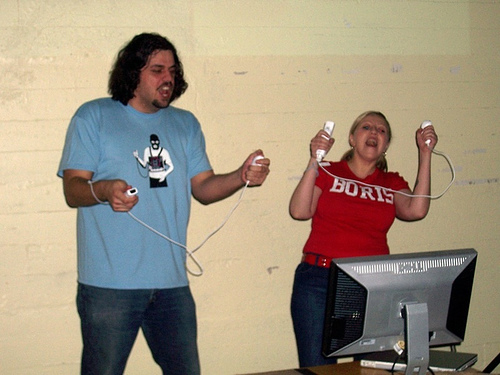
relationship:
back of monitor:
[369, 272, 454, 302] [322, 248, 480, 359]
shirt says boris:
[302, 160, 410, 261] [328, 174, 395, 207]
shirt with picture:
[57, 98, 215, 290] [132, 132, 177, 188]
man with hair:
[58, 34, 271, 375] [108, 32, 188, 108]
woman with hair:
[287, 110, 439, 370] [342, 110, 391, 174]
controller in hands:
[125, 186, 140, 197] [100, 150, 272, 214]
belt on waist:
[300, 251, 332, 270] [302, 241, 393, 275]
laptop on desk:
[360, 352, 479, 372] [234, 362, 489, 374]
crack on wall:
[453, 179, 500, 185] [443, 7, 500, 194]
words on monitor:
[398, 259, 424, 273] [322, 248, 480, 359]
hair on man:
[108, 32, 188, 108] [58, 34, 271, 375]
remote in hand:
[315, 121, 337, 161] [307, 131, 335, 157]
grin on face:
[367, 136, 380, 150] [358, 118, 389, 161]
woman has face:
[287, 110, 439, 370] [358, 118, 389, 161]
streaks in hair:
[378, 157, 387, 174] [108, 32, 188, 108]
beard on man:
[150, 99, 172, 110] [58, 34, 271, 375]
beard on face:
[150, 99, 172, 110] [150, 52, 176, 107]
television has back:
[323, 246, 479, 360] [369, 272, 454, 302]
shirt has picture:
[57, 98, 215, 290] [132, 132, 175, 190]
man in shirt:
[58, 34, 271, 375] [57, 98, 215, 290]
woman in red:
[287, 110, 439, 370] [346, 235, 371, 252]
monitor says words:
[322, 248, 480, 359] [394, 259, 424, 273]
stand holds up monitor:
[402, 302, 431, 374] [322, 248, 480, 359]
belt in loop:
[300, 251, 332, 270] [313, 251, 322, 265]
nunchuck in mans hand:
[245, 154, 265, 189] [237, 148, 272, 189]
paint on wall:
[414, 78, 432, 101] [443, 7, 500, 194]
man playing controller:
[55, 34, 271, 375] [312, 121, 336, 164]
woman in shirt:
[287, 110, 439, 370] [302, 160, 410, 261]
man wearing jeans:
[58, 34, 271, 375] [76, 281, 203, 374]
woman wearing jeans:
[287, 110, 439, 370] [289, 252, 337, 367]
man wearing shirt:
[58, 34, 271, 375] [302, 160, 410, 261]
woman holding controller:
[287, 110, 439, 370] [315, 121, 335, 164]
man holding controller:
[58, 34, 271, 375] [125, 186, 140, 197]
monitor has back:
[322, 248, 480, 359] [369, 272, 454, 302]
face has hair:
[150, 52, 176, 107] [150, 84, 178, 110]